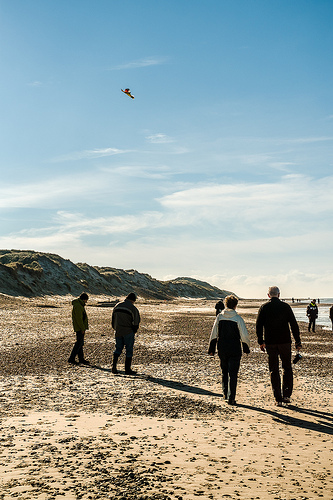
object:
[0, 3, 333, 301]
sky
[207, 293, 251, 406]
people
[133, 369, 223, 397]
shade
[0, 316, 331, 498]
beach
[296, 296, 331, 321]
water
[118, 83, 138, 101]
object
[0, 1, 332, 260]
air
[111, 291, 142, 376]
these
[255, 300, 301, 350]
sweater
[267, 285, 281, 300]
hair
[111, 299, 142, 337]
jacket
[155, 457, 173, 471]
rocks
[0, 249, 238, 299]
dunes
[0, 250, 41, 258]
plants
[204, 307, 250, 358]
sweater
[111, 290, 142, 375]
man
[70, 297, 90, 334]
jacket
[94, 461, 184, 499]
stones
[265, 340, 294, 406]
trouser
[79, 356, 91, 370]
shoe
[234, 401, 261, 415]
edge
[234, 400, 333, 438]
shadow